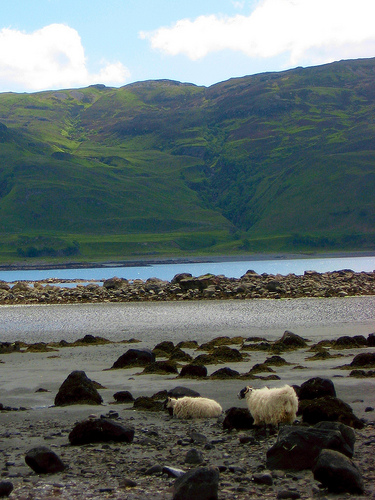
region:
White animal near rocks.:
[160, 353, 229, 430]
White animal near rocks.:
[232, 361, 323, 461]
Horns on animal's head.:
[241, 368, 254, 404]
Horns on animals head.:
[154, 399, 199, 441]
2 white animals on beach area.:
[151, 356, 305, 446]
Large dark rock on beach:
[315, 446, 362, 495]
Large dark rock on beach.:
[82, 421, 159, 471]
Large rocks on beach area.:
[115, 339, 201, 393]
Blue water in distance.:
[130, 233, 251, 279]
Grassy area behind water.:
[52, 233, 157, 262]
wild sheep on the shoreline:
[161, 384, 300, 459]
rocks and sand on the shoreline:
[51, 363, 167, 470]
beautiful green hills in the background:
[54, 186, 291, 257]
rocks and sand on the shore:
[56, 364, 111, 417]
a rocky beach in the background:
[41, 260, 320, 313]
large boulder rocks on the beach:
[54, 364, 103, 418]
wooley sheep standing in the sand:
[231, 370, 302, 434]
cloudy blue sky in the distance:
[36, 43, 153, 84]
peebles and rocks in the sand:
[47, 411, 199, 494]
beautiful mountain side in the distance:
[24, 87, 299, 219]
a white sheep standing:
[237, 382, 304, 425]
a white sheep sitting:
[158, 392, 225, 424]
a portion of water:
[12, 309, 81, 334]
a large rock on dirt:
[14, 441, 66, 472]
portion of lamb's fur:
[256, 391, 283, 413]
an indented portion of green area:
[181, 152, 288, 231]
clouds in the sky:
[168, 23, 335, 53]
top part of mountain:
[130, 73, 195, 91]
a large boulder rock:
[178, 274, 224, 289]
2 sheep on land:
[155, 378, 317, 440]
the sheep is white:
[223, 387, 289, 471]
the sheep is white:
[224, 387, 271, 436]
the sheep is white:
[225, 407, 249, 432]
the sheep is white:
[244, 383, 285, 439]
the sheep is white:
[241, 381, 316, 494]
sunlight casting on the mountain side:
[34, 111, 128, 150]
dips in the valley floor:
[172, 171, 269, 216]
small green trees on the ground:
[6, 217, 87, 257]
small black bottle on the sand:
[146, 459, 212, 487]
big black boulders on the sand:
[66, 408, 251, 495]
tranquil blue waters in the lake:
[46, 260, 275, 278]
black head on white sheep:
[231, 382, 256, 398]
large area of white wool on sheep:
[249, 381, 320, 419]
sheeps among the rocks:
[149, 374, 329, 433]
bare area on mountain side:
[59, 103, 137, 135]